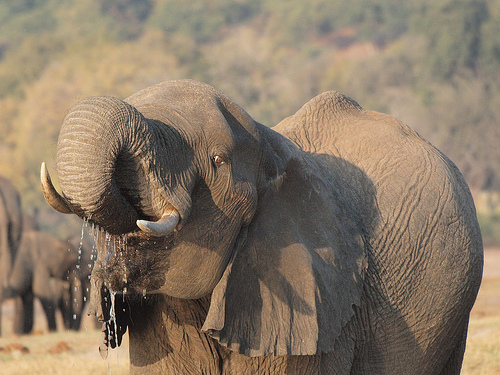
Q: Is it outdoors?
A: Yes, it is outdoors.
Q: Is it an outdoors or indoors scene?
A: It is outdoors.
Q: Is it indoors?
A: No, it is outdoors.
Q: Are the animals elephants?
A: Yes, all the animals are elephants.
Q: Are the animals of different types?
A: No, all the animals are elephants.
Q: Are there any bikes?
A: No, there are no bikes.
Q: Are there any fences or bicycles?
A: No, there are no bicycles or fences.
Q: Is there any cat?
A: No, there are no cats.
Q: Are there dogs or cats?
A: No, there are no cats or dogs.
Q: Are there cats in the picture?
A: No, there are no cats.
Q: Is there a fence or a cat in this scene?
A: No, there are no cats or fences.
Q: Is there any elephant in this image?
A: Yes, there are elephants.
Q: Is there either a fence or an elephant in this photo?
A: Yes, there are elephants.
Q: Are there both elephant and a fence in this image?
A: No, there are elephants but no fences.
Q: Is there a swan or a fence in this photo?
A: No, there are no fences or swans.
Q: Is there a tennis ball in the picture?
A: No, there are no tennis balls.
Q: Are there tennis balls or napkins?
A: No, there are no tennis balls or napkins.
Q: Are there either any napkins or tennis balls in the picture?
A: No, there are no tennis balls or napkins.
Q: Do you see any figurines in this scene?
A: No, there are no figurines.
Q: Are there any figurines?
A: No, there are no figurines.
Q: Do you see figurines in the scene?
A: No, there are no figurines.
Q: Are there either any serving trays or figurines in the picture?
A: No, there are no figurines or serving trays.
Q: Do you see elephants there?
A: Yes, there is an elephant.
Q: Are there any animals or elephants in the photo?
A: Yes, there is an elephant.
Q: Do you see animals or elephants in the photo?
A: Yes, there is an elephant.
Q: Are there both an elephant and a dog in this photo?
A: No, there is an elephant but no dogs.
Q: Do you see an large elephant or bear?
A: Yes, there is a large elephant.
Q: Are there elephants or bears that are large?
A: Yes, the elephant is large.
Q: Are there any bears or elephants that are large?
A: Yes, the elephant is large.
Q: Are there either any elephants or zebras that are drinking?
A: Yes, the elephant is drinking.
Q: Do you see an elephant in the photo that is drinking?
A: Yes, there is an elephant that is drinking.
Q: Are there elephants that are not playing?
A: Yes, there is an elephant that is drinking.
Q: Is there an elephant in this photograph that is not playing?
A: Yes, there is an elephant that is drinking.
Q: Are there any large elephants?
A: Yes, there is a large elephant.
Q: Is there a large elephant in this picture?
A: Yes, there is a large elephant.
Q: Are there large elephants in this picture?
A: Yes, there is a large elephant.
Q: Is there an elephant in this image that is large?
A: Yes, there is an elephant that is large.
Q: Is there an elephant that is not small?
A: Yes, there is a large elephant.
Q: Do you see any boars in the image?
A: No, there are no boars.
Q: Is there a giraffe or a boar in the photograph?
A: No, there are no boars or giraffes.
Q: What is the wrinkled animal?
A: The animal is an elephant.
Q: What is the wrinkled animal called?
A: The animal is an elephant.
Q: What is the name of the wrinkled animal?
A: The animal is an elephant.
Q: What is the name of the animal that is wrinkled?
A: The animal is an elephant.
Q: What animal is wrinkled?
A: The animal is an elephant.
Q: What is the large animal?
A: The animal is an elephant.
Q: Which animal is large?
A: The animal is an elephant.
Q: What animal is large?
A: The animal is an elephant.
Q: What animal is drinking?
A: The animal is an elephant.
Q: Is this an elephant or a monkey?
A: This is an elephant.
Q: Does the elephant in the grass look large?
A: Yes, the elephant is large.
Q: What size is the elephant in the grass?
A: The elephant is large.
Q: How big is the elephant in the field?
A: The elephant is large.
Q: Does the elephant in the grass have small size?
A: No, the elephant is large.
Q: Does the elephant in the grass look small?
A: No, the elephant is large.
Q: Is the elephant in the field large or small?
A: The elephant is large.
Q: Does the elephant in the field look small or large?
A: The elephant is large.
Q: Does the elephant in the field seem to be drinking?
A: Yes, the elephant is drinking.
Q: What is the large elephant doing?
A: The elephant is drinking.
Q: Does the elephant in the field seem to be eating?
A: No, the elephant is drinking.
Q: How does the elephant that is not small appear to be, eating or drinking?
A: The elephant is drinking.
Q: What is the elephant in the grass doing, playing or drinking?
A: The elephant is drinking.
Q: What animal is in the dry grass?
A: The elephant is in the grass.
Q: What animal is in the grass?
A: The elephant is in the grass.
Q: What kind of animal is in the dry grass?
A: The animal is an elephant.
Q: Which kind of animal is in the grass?
A: The animal is an elephant.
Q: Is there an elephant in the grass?
A: Yes, there is an elephant in the grass.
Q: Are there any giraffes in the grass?
A: No, there is an elephant in the grass.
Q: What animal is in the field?
A: The animal is an elephant.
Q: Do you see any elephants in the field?
A: Yes, there is an elephant in the field.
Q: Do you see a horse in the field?
A: No, there is an elephant in the field.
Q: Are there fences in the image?
A: No, there are no fences.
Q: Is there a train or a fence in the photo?
A: No, there are no fences or trains.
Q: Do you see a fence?
A: No, there are no fences.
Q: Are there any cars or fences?
A: No, there are no fences or cars.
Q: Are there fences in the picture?
A: No, there are no fences.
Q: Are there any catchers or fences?
A: No, there are no fences or catchers.